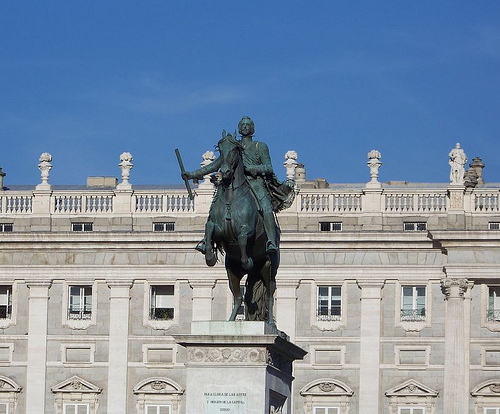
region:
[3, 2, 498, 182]
blue of daytime sky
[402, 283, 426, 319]
window with closed curtains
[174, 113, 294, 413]
statue on cement base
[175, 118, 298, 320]
statue of man on horse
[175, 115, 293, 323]
statue with jumping horse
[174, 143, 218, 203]
baton in statue hand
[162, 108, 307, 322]
statue atop concrete pedestal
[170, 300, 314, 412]
concrete pedestal holding statue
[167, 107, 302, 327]
statue of man on horseback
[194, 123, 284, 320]
statue of horse with front legs raised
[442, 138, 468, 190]
statue of person atop building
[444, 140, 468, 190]
statue of person on building roof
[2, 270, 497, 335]
row of windows on building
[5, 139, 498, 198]
decorative statues along rooftop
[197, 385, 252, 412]
inscription on concrete pedestal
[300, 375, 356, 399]
decorative arch above window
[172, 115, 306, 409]
statue of man and horse on a pedestal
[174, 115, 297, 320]
statue of a man riding a horse with a stick in his hand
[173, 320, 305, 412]
words carved into the statue pedestal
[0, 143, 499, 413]
big building behind the statue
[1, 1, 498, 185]
clear sky above the old building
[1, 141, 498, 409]
Big building with multiple windows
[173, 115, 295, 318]
statue of man riding a horse on its hind legs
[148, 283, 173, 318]
window left wide open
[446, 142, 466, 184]
statue of a man on top of the building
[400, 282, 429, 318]
closed window with the shades down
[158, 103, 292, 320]
green statue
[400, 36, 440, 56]
white clouds in blue sky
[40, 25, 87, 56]
white clouds in blue sky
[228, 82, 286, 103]
white clouds in blue sky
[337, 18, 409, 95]
white clouds in blue sky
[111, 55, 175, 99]
white clouds in blue sky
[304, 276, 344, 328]
window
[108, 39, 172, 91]
white clouds in blue sky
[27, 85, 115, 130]
white clouds in blue sky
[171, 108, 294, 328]
statue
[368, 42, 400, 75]
white clouds in blue sky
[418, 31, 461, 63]
white clouds in blue sky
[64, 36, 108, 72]
white clouds in blue sky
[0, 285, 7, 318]
window on white building facing statue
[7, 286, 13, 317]
window on white building facing statue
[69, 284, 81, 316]
window on white building facing statue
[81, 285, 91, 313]
window on white building facing statue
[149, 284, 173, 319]
window on white building facing statue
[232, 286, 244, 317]
window on white building facing statue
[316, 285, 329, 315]
window on white building facing statue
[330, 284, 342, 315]
window on white building facing statue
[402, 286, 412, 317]
window on white building facing statue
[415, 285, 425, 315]
window on white building facing statue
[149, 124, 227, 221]
Sword in hand of the statue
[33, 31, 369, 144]
Light clouds in the otherwise blue sky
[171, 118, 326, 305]
Large statue on top of concrete column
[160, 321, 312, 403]
Writing on the column under the statue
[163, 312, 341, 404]
Large column underneath the large statue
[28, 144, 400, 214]
Large posts and barriers on the top of the building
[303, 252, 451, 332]
Windows on the side of the concrete building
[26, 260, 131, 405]
Designs on the side of the concrete building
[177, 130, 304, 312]
Statue on the horse with a sword in his hand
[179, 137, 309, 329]
Horse has its front feet on the air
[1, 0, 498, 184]
Clear blue sky with no clouds